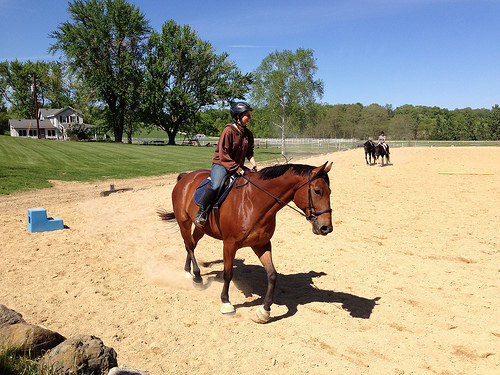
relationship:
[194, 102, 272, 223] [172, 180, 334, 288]
rider on horse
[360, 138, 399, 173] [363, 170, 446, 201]
horses on dirt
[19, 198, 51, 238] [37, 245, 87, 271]
step on dirt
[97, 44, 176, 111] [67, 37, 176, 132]
leaves on trees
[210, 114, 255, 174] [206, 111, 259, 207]
jacket on rider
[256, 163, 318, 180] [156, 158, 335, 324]
mane on horse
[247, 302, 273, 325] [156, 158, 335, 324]
shoe on horse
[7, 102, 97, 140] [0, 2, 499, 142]
house in background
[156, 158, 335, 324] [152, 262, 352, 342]
horse on sand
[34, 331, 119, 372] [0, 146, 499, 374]
rock on side of arena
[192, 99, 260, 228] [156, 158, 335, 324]
person riding horse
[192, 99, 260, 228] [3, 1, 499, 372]
person in rural area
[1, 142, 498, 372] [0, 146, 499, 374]
arena has a arena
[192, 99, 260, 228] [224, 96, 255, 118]
person wearing helmet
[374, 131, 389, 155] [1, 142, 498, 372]
person in arena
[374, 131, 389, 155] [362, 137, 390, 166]
person with extra horse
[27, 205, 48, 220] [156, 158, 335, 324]
step to get on horse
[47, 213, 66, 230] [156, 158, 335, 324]
step to get on horse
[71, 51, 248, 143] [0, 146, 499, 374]
trees on arena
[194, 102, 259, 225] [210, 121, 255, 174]
rider wearing jacket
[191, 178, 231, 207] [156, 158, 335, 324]
blanket on horse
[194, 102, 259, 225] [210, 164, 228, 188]
rider wearing blue jeans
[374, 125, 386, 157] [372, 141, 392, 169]
person riding horse